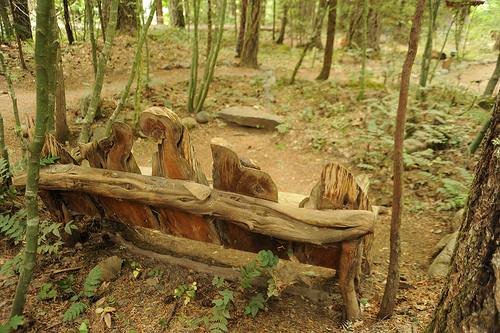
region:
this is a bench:
[55, 125, 370, 255]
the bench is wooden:
[64, 98, 368, 250]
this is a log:
[135, 108, 202, 179]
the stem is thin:
[23, 12, 60, 97]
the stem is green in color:
[25, 17, 57, 103]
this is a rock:
[215, 103, 280, 125]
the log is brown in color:
[146, 115, 186, 172]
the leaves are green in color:
[227, 233, 281, 313]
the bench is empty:
[85, 130, 369, 224]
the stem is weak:
[390, 58, 422, 123]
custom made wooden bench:
[30, 100, 379, 305]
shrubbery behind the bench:
[0, 195, 300, 331]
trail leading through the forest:
[1, 55, 498, 127]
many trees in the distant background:
[0, 0, 499, 62]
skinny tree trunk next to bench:
[371, 0, 428, 325]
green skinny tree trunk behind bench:
[6, 0, 53, 321]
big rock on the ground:
[216, 98, 283, 129]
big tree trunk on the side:
[421, 75, 499, 330]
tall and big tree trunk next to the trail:
[238, 0, 260, 72]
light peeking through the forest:
[0, 0, 295, 32]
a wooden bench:
[20, 111, 389, 306]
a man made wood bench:
[27, 123, 389, 314]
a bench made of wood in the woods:
[31, 116, 395, 313]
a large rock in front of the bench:
[217, 92, 279, 132]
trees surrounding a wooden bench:
[4, 3, 499, 317]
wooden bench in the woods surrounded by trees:
[2, 1, 488, 328]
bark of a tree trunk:
[433, 127, 498, 324]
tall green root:
[16, 1, 57, 304]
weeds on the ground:
[0, 73, 487, 328]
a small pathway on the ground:
[1, 73, 491, 114]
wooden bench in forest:
[37, 103, 394, 324]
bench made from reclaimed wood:
[37, 102, 363, 314]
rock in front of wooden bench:
[219, 96, 282, 133]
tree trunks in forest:
[5, 3, 499, 303]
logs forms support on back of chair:
[42, 164, 359, 287]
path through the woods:
[18, 46, 483, 108]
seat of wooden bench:
[120, 155, 355, 217]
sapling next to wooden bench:
[379, 40, 416, 310]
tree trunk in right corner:
[443, 104, 499, 322]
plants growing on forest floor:
[25, 75, 482, 320]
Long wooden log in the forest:
[15, 167, 376, 236]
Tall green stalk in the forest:
[12, 5, 51, 318]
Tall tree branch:
[381, 4, 425, 321]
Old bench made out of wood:
[25, 105, 380, 317]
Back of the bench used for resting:
[29, 107, 375, 284]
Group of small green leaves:
[41, 265, 114, 322]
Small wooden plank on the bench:
[211, 145, 278, 252]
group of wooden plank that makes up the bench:
[59, 111, 371, 263]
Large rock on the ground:
[219, 101, 285, 126]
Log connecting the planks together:
[13, 163, 378, 244]